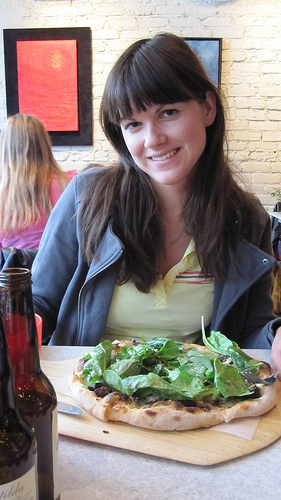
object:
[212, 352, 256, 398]
spinach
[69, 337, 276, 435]
crust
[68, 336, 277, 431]
pizza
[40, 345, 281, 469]
board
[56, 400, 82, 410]
edge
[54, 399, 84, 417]
knife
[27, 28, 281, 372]
woman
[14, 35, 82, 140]
picture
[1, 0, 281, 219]
wall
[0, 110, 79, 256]
woman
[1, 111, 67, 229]
hair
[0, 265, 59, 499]
bottle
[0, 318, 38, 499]
bottle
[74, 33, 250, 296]
hair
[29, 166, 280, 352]
jacket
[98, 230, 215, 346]
shirt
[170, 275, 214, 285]
stripes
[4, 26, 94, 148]
frame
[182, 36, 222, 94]
picture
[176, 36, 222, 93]
frame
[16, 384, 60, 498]
beer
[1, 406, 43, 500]
beer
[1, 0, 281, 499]
photo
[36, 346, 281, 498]
table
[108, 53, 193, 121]
bangs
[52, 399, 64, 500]
label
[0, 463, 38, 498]
label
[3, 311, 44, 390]
cup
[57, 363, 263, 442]
napkin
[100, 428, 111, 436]
crumb